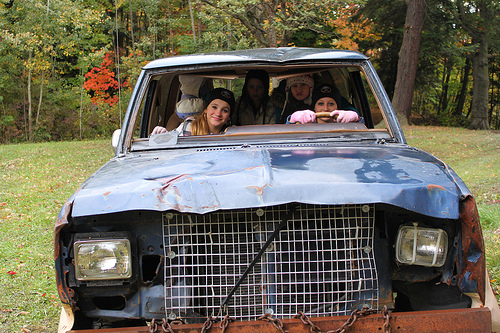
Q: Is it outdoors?
A: Yes, it is outdoors.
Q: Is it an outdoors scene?
A: Yes, it is outdoors.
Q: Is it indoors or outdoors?
A: It is outdoors.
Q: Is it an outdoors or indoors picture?
A: It is outdoors.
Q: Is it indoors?
A: No, it is outdoors.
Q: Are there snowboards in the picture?
A: No, there are no snowboards.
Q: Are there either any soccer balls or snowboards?
A: No, there are no snowboards or soccer balls.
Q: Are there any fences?
A: No, there are no fences.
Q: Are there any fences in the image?
A: No, there are no fences.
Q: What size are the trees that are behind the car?
A: The trees are large.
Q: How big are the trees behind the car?
A: The trees are large.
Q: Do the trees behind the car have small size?
A: No, the trees are large.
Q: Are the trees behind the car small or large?
A: The trees are large.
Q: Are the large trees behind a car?
A: Yes, the trees are behind a car.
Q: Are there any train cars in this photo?
A: No, there are no train cars.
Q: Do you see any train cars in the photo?
A: No, there are no train cars.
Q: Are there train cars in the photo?
A: No, there are no train cars.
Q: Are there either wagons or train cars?
A: No, there are no train cars or wagons.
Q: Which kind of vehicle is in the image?
A: The vehicle is a car.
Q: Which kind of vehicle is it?
A: The vehicle is a car.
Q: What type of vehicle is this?
A: This is a car.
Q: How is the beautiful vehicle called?
A: The vehicle is a car.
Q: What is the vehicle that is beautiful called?
A: The vehicle is a car.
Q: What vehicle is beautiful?
A: The vehicle is a car.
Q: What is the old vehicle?
A: The vehicle is a car.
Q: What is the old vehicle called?
A: The vehicle is a car.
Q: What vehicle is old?
A: The vehicle is a car.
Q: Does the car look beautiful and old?
A: Yes, the car is beautiful and old.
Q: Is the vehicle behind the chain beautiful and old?
A: Yes, the car is beautiful and old.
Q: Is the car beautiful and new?
A: No, the car is beautiful but old.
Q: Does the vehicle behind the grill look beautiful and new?
A: No, the car is beautiful but old.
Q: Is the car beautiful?
A: Yes, the car is beautiful.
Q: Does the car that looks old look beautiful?
A: Yes, the car is beautiful.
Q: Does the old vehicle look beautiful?
A: Yes, the car is beautiful.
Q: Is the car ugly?
A: No, the car is beautiful.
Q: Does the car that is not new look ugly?
A: No, the car is beautiful.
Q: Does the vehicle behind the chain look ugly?
A: No, the car is beautiful.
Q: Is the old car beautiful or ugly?
A: The car is beautiful.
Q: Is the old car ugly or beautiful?
A: The car is beautiful.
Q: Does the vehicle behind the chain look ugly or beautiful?
A: The car is beautiful.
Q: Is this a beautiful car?
A: Yes, this is a beautiful car.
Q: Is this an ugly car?
A: No, this is a beautiful car.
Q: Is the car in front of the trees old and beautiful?
A: Yes, the car is old and beautiful.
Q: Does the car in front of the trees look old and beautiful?
A: Yes, the car is old and beautiful.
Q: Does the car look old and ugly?
A: No, the car is old but beautiful.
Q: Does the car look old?
A: Yes, the car is old.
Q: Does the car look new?
A: No, the car is old.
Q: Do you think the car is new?
A: No, the car is old.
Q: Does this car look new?
A: No, the car is old.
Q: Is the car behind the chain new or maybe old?
A: The car is old.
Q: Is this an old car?
A: Yes, this is an old car.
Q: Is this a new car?
A: No, this is an old car.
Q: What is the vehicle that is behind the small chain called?
A: The vehicle is a car.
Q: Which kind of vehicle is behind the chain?
A: The vehicle is a car.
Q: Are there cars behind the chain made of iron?
A: Yes, there is a car behind the chain.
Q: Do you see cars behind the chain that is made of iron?
A: Yes, there is a car behind the chain.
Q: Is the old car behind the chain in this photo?
A: Yes, the car is behind the chain.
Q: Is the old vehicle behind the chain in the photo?
A: Yes, the car is behind the chain.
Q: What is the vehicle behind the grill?
A: The vehicle is a car.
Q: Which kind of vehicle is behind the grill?
A: The vehicle is a car.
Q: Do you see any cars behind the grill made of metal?
A: Yes, there is a car behind the grill.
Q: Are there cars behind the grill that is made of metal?
A: Yes, there is a car behind the grill.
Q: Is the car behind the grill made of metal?
A: Yes, the car is behind the grill.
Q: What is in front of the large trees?
A: The car is in front of the trees.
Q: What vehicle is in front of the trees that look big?
A: The vehicle is a car.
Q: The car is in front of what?
A: The car is in front of the trees.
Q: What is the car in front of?
A: The car is in front of the trees.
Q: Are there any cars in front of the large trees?
A: Yes, there is a car in front of the trees.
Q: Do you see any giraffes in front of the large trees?
A: No, there is a car in front of the trees.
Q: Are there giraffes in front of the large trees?
A: No, there is a car in front of the trees.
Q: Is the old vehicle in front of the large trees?
A: Yes, the car is in front of the trees.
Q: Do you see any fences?
A: No, there are no fences.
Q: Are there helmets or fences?
A: No, there are no fences or helmets.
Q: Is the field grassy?
A: Yes, the field is grassy.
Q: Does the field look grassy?
A: Yes, the field is grassy.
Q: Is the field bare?
A: No, the field is grassy.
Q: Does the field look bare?
A: No, the field is grassy.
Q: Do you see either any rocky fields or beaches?
A: No, there is a field but it is grassy.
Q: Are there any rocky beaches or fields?
A: No, there is a field but it is grassy.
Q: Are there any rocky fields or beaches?
A: No, there is a field but it is grassy.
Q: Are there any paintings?
A: No, there are no paintings.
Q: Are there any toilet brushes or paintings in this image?
A: No, there are no paintings or toilet brushes.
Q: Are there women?
A: Yes, there is a woman.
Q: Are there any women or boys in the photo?
A: Yes, there is a woman.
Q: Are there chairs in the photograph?
A: No, there are no chairs.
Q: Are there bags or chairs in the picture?
A: No, there are no chairs or bags.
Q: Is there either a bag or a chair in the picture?
A: No, there are no chairs or bags.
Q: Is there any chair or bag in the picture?
A: No, there are no chairs or bags.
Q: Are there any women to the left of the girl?
A: Yes, there is a woman to the left of the girl.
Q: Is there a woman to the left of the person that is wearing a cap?
A: Yes, there is a woman to the left of the girl.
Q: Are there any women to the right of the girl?
A: No, the woman is to the left of the girl.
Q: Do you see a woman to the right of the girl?
A: No, the woman is to the left of the girl.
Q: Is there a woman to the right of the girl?
A: No, the woman is to the left of the girl.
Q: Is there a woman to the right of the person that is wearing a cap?
A: No, the woman is to the left of the girl.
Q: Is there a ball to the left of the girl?
A: No, there is a woman to the left of the girl.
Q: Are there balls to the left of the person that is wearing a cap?
A: No, there is a woman to the left of the girl.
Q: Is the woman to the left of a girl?
A: Yes, the woman is to the left of a girl.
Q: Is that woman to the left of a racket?
A: No, the woman is to the left of a girl.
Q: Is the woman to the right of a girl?
A: No, the woman is to the left of a girl.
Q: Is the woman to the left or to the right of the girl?
A: The woman is to the left of the girl.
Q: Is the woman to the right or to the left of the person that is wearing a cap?
A: The woman is to the left of the girl.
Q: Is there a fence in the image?
A: No, there are no fences.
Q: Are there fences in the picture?
A: No, there are no fences.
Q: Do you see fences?
A: No, there are no fences.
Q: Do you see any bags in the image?
A: No, there are no bags.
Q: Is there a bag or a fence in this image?
A: No, there are no bags or fences.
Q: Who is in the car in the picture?
A: The people are in the car.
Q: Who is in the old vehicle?
A: The people are in the car.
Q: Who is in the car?
A: The people are in the car.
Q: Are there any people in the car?
A: Yes, there are people in the car.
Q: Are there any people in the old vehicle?
A: Yes, there are people in the car.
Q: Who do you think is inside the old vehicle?
A: The people are inside the car.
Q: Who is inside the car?
A: The people are inside the car.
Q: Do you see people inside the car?
A: Yes, there are people inside the car.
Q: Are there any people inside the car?
A: Yes, there are people inside the car.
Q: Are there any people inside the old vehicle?
A: Yes, there are people inside the car.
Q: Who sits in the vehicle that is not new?
A: The people sit in the car.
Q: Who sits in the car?
A: The people sit in the car.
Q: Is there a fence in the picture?
A: No, there are no fences.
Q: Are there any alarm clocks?
A: No, there are no alarm clocks.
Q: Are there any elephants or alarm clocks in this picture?
A: No, there are no alarm clocks or elephants.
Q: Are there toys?
A: No, there are no toys.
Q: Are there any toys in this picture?
A: No, there are no toys.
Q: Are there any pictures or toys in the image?
A: No, there are no toys or pictures.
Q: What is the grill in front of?
A: The grill is in front of the car.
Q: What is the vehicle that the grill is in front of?
A: The vehicle is a car.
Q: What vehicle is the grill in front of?
A: The grill is in front of the car.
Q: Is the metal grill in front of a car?
A: Yes, the grill is in front of a car.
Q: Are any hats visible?
A: Yes, there is a hat.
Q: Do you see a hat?
A: Yes, there is a hat.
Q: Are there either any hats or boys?
A: Yes, there is a hat.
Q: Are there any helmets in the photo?
A: No, there are no helmets.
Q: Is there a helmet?
A: No, there are no helmets.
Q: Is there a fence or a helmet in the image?
A: No, there are no helmets or fences.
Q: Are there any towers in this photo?
A: No, there are no towers.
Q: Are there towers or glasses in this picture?
A: No, there are no towers or glasses.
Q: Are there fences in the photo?
A: No, there are no fences.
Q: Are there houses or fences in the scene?
A: No, there are no fences or houses.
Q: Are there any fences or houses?
A: No, there are no fences or houses.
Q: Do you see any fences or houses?
A: No, there are no fences or houses.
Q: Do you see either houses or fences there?
A: No, there are no fences or houses.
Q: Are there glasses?
A: No, there are no glasses.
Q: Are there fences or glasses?
A: No, there are no glasses or fences.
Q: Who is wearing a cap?
A: The girl is wearing a cap.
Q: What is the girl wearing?
A: The girl is wearing a cap.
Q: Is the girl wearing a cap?
A: Yes, the girl is wearing a cap.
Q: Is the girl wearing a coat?
A: No, the girl is wearing a cap.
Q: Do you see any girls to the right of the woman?
A: Yes, there is a girl to the right of the woman.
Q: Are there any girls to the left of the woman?
A: No, the girl is to the right of the woman.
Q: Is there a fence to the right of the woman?
A: No, there is a girl to the right of the woman.